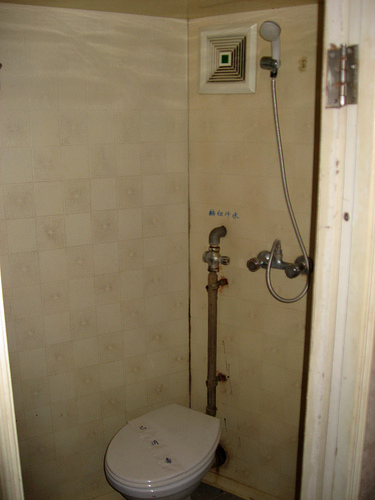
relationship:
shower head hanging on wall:
[257, 20, 282, 69] [0, 0, 370, 498]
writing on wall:
[183, 206, 260, 231] [187, 4, 318, 498]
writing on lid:
[139, 423, 175, 468] [127, 416, 180, 473]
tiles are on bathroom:
[42, 257, 158, 344] [1, 0, 373, 499]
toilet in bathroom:
[104, 399, 223, 497] [1, 1, 324, 499]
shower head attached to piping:
[259, 19, 285, 79] [264, 78, 311, 308]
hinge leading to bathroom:
[321, 39, 365, 111] [1, 0, 373, 499]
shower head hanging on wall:
[259, 19, 281, 78] [186, 3, 373, 498]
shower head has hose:
[259, 19, 281, 78] [265, 71, 311, 304]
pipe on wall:
[197, 223, 230, 421] [19, 32, 173, 284]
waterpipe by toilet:
[203, 223, 229, 413] [104, 399, 223, 497]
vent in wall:
[196, 22, 257, 92] [187, 4, 318, 498]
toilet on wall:
[104, 399, 223, 497] [1, 0, 321, 498]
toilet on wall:
[104, 399, 223, 497] [204, 102, 266, 223]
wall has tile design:
[21, 78, 151, 184] [12, 193, 173, 291]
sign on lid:
[133, 416, 186, 481] [104, 402, 220, 483]